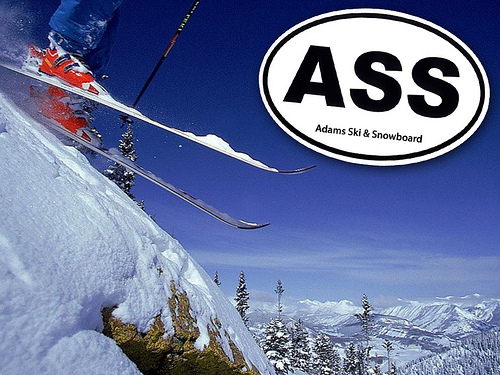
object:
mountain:
[230, 292, 500, 375]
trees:
[235, 270, 365, 375]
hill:
[0, 92, 273, 375]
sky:
[190, 153, 474, 311]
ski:
[0, 63, 316, 177]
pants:
[48, 0, 121, 58]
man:
[21, 0, 120, 147]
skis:
[23, 120, 270, 230]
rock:
[130, 286, 238, 375]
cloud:
[428, 241, 467, 283]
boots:
[21, 44, 100, 94]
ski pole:
[118, 0, 200, 124]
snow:
[201, 128, 260, 158]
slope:
[19, 128, 210, 346]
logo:
[283, 44, 461, 144]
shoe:
[20, 85, 103, 147]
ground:
[70, 303, 467, 374]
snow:
[40, 232, 193, 289]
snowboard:
[371, 130, 422, 143]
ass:
[282, 44, 459, 117]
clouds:
[263, 258, 299, 283]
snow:
[273, 335, 287, 359]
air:
[134, 53, 246, 204]